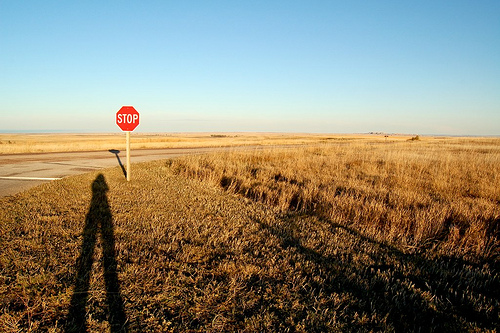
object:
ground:
[0, 133, 499, 330]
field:
[0, 140, 499, 333]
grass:
[0, 131, 497, 333]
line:
[0, 176, 64, 183]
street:
[0, 144, 257, 199]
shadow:
[150, 238, 279, 292]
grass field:
[0, 127, 497, 154]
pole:
[125, 131, 131, 182]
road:
[0, 144, 292, 199]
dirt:
[8, 147, 178, 161]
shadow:
[61, 173, 125, 333]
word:
[117, 113, 139, 124]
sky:
[0, 0, 498, 137]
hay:
[355, 172, 410, 229]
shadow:
[108, 148, 127, 178]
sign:
[115, 105, 140, 131]